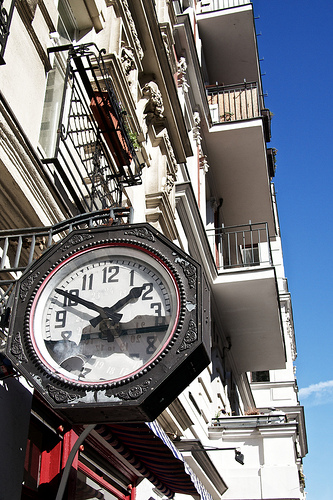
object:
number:
[102, 266, 119, 283]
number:
[61, 330, 72, 353]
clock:
[5, 223, 211, 418]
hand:
[51, 285, 122, 324]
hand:
[91, 281, 150, 323]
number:
[55, 310, 67, 328]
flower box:
[86, 83, 134, 173]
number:
[129, 269, 134, 286]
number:
[63, 288, 79, 307]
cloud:
[301, 384, 333, 399]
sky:
[288, 6, 332, 303]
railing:
[208, 81, 262, 121]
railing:
[213, 225, 270, 271]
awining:
[142, 422, 218, 497]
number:
[151, 303, 161, 319]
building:
[4, 5, 309, 498]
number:
[141, 282, 154, 300]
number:
[82, 273, 93, 290]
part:
[302, 391, 309, 398]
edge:
[196, 258, 209, 362]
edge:
[258, 121, 278, 233]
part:
[282, 448, 289, 457]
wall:
[231, 471, 256, 498]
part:
[226, 134, 233, 143]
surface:
[223, 136, 262, 217]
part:
[260, 467, 279, 498]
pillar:
[256, 438, 300, 500]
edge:
[194, 8, 258, 21]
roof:
[196, 9, 257, 80]